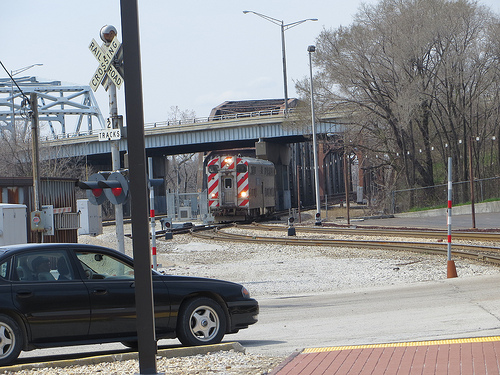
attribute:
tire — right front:
[175, 291, 229, 348]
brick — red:
[296, 350, 498, 374]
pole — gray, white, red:
[433, 158, 460, 280]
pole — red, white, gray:
[138, 157, 167, 281]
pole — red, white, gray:
[295, 42, 332, 226]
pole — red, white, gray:
[19, 94, 52, 251]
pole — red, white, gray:
[102, 100, 131, 280]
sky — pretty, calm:
[2, 0, 497, 135]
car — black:
[2, 227, 274, 369]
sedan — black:
[14, 248, 274, 337]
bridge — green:
[2, 71, 383, 163]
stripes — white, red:
[202, 158, 225, 206]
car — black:
[3, 243, 267, 369]